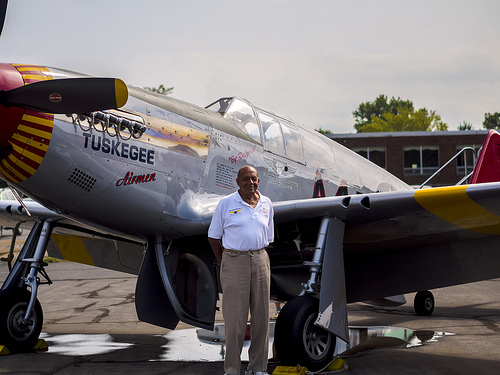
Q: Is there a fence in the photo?
A: No, there are no fences.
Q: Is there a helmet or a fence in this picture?
A: No, there are no fences or helmets.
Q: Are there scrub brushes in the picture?
A: No, there are no scrub brushes.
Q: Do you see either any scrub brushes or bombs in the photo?
A: No, there are no scrub brushes or bombs.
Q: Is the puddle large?
A: Yes, the puddle is large.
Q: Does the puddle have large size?
A: Yes, the puddle is large.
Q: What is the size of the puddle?
A: The puddle is large.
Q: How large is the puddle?
A: The puddle is large.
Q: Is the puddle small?
A: No, the puddle is large.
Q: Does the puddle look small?
A: No, the puddle is large.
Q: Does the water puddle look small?
A: No, the puddle is large.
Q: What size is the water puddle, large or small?
A: The puddle is large.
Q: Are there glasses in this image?
A: No, there are no glasses.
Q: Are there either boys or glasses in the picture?
A: No, there are no glasses or boys.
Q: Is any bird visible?
A: No, there are no birds.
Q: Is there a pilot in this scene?
A: No, there are no pilots.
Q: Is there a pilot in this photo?
A: No, there are no pilots.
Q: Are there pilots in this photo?
A: No, there are no pilots.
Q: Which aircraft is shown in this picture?
A: The aircraft is a jet.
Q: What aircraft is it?
A: The aircraft is a jet.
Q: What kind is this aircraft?
A: This is a jet.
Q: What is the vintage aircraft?
A: The aircraft is a jet.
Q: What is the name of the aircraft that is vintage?
A: The aircraft is a jet.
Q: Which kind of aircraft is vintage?
A: The aircraft is a jet.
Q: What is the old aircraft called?
A: The aircraft is a jet.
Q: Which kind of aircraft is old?
A: The aircraft is a jet.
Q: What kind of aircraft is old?
A: The aircraft is a jet.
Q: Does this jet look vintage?
A: Yes, the jet is vintage.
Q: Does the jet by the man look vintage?
A: Yes, the jet is vintage.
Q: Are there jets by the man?
A: Yes, there is a jet by the man.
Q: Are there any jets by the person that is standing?
A: Yes, there is a jet by the man.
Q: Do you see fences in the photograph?
A: No, there are no fences.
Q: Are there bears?
A: No, there are no bears.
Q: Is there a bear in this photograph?
A: No, there are no bears.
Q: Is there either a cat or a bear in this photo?
A: No, there are no bears or cats.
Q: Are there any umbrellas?
A: No, there are no umbrellas.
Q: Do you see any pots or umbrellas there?
A: No, there are no umbrellas or pots.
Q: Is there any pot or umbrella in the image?
A: No, there are no umbrellas or pots.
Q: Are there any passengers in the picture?
A: No, there are no passengers.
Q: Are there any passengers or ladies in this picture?
A: No, there are no passengers or ladies.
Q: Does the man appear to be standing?
A: Yes, the man is standing.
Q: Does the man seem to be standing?
A: Yes, the man is standing.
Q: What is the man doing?
A: The man is standing.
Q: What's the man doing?
A: The man is standing.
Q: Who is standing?
A: The man is standing.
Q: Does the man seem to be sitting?
A: No, the man is standing.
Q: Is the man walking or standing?
A: The man is standing.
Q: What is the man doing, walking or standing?
A: The man is standing.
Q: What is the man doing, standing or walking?
A: The man is standing.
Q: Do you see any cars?
A: No, there are no cars.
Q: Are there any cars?
A: No, there are no cars.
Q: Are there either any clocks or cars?
A: No, there are no cars or clocks.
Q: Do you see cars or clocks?
A: No, there are no cars or clocks.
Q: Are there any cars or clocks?
A: No, there are no cars or clocks.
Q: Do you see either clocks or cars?
A: No, there are no cars or clocks.